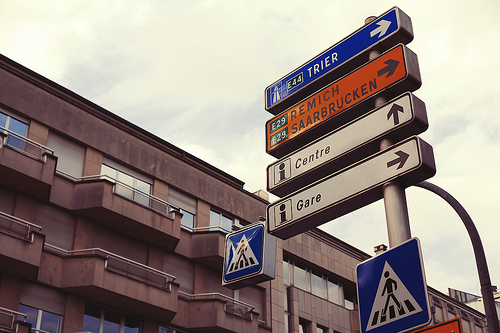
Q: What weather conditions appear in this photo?
A: It is cloudy.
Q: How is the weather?
A: It is cloudy.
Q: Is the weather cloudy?
A: Yes, it is cloudy.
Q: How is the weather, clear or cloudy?
A: It is cloudy.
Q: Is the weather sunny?
A: No, it is cloudy.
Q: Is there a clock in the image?
A: No, there are no clocks.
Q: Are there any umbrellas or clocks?
A: No, there are no clocks or umbrellas.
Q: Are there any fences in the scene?
A: No, there are no fences.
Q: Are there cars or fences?
A: No, there are no fences or cars.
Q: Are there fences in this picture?
A: No, there are no fences.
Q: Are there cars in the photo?
A: No, there are no cars.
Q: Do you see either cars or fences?
A: No, there are no cars or fences.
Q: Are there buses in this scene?
A: No, there are no buses.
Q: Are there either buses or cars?
A: No, there are no buses or cars.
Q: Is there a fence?
A: No, there are no fences.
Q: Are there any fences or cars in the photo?
A: No, there are no fences or cars.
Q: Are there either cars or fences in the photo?
A: No, there are no fences or cars.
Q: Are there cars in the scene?
A: No, there are no cars.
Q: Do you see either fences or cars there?
A: No, there are no cars or fences.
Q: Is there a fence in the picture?
A: No, there are no fences.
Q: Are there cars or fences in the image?
A: No, there are no fences or cars.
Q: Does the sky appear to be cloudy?
A: Yes, the sky is cloudy.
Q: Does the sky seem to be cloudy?
A: Yes, the sky is cloudy.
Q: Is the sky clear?
A: No, the sky is cloudy.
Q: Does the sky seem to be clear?
A: No, the sky is cloudy.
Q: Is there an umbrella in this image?
A: No, there are no umbrellas.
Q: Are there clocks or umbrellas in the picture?
A: No, there are no umbrellas or clocks.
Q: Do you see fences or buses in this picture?
A: No, there are no fences or buses.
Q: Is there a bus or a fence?
A: No, there are no fences or buses.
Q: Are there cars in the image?
A: No, there are no cars.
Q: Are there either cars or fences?
A: No, there are no cars or fences.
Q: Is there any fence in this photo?
A: No, there are no fences.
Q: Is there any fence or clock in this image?
A: No, there are no fences or clocks.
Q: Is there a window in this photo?
A: Yes, there is a window.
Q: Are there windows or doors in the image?
A: Yes, there is a window.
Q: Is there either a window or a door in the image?
A: Yes, there is a window.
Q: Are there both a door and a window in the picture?
A: No, there is a window but no doors.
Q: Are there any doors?
A: No, there are no doors.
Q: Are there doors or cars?
A: No, there are no doors or cars.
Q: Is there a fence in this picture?
A: No, there are no fences.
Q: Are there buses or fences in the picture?
A: No, there are no fences or buses.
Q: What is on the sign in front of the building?
A: The arrow is on the sign.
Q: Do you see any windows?
A: Yes, there is a window.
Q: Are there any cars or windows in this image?
A: Yes, there is a window.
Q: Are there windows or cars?
A: Yes, there is a window.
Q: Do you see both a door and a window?
A: No, there is a window but no doors.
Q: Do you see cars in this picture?
A: No, there are no cars.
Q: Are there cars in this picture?
A: No, there are no cars.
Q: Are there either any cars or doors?
A: No, there are no cars or doors.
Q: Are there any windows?
A: Yes, there is a window.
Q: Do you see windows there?
A: Yes, there is a window.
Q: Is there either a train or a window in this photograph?
A: Yes, there is a window.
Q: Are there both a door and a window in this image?
A: No, there is a window but no doors.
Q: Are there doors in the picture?
A: No, there are no doors.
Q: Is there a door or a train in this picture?
A: No, there are no doors or trains.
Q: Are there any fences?
A: No, there are no fences.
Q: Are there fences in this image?
A: No, there are no fences.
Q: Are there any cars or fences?
A: No, there are no fences or cars.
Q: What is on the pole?
A: The sign is on the pole.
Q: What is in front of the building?
A: The sign is in front of the building.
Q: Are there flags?
A: No, there are no flags.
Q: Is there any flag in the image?
A: No, there are no flags.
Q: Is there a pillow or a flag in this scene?
A: No, there are no flags or pillows.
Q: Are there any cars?
A: No, there are no cars.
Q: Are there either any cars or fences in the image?
A: No, there are no cars or fences.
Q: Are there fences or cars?
A: No, there are no cars or fences.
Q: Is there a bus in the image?
A: No, there are no buses.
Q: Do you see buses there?
A: No, there are no buses.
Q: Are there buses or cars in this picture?
A: No, there are no buses or cars.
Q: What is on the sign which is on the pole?
A: The arrow is on the sign.